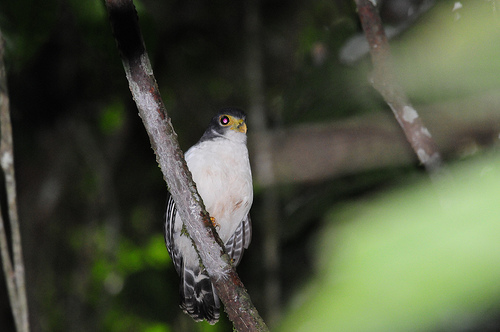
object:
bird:
[163, 106, 255, 326]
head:
[211, 108, 249, 143]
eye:
[218, 115, 230, 126]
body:
[183, 137, 254, 265]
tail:
[175, 269, 221, 325]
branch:
[104, 1, 269, 332]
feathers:
[162, 138, 254, 326]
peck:
[236, 121, 247, 134]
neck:
[201, 129, 249, 143]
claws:
[209, 219, 217, 227]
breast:
[182, 138, 254, 205]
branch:
[253, 93, 498, 192]